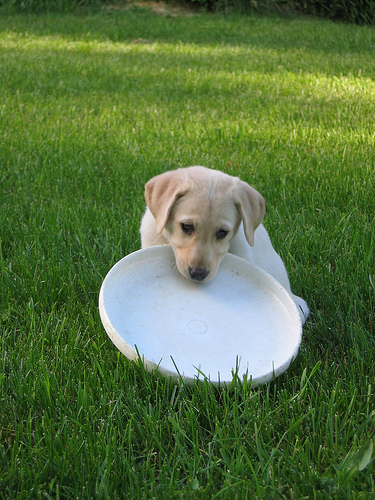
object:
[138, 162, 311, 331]
dog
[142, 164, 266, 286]
head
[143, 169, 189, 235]
ear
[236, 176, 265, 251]
ear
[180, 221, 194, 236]
eye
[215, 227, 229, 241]
eye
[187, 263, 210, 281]
nose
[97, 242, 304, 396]
frisbee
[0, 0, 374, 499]
grass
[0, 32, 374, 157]
light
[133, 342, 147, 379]
blade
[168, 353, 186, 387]
blade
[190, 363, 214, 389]
blade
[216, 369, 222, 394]
blade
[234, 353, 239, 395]
blade